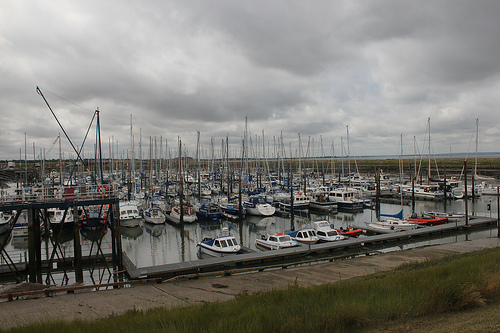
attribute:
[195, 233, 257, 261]
boat — small, parked, white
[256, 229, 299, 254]
boat — small, parked, white, black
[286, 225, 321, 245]
boat — small, parked, blue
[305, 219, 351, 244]
boat — small, parked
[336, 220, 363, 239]
boat — small, parked, red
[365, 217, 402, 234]
boat — small, parked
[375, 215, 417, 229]
boat — small, parked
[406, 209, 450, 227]
boat — small, parked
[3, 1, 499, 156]
clouds — gray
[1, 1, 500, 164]
sky — cloudy, overcast, grey, threatening, gloomy, heavy, sunless, hazy, precarious, dismal